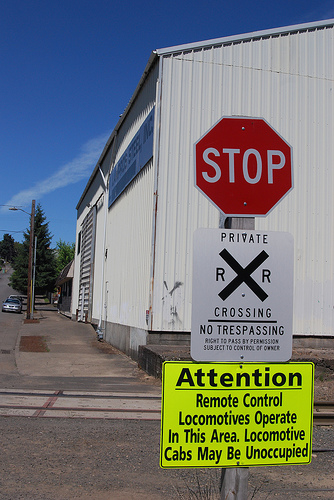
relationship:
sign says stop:
[191, 112, 296, 221] [202, 144, 287, 187]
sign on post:
[193, 228, 294, 364] [220, 216, 258, 494]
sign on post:
[159, 362, 310, 465] [220, 216, 258, 494]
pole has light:
[29, 201, 35, 321] [7, 208, 19, 213]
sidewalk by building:
[16, 312, 150, 374] [77, 18, 330, 339]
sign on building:
[105, 110, 161, 208] [77, 18, 330, 339]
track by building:
[2, 386, 330, 423] [77, 18, 330, 339]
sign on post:
[191, 112, 296, 221] [220, 216, 258, 494]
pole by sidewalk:
[32, 240, 37, 320] [16, 312, 150, 374]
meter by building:
[92, 324, 109, 341] [77, 18, 330, 339]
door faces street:
[78, 218, 91, 321] [0, 254, 18, 375]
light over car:
[7, 208, 19, 213] [1, 299, 21, 315]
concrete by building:
[138, 340, 333, 380] [77, 18, 330, 339]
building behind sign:
[77, 18, 330, 339] [191, 112, 296, 221]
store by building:
[53, 264, 72, 311] [77, 18, 330, 339]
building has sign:
[77, 18, 330, 339] [105, 110, 161, 208]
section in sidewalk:
[18, 336, 45, 351] [16, 312, 150, 374]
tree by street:
[12, 206, 59, 295] [0, 254, 18, 375]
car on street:
[1, 299, 21, 315] [0, 254, 18, 375]